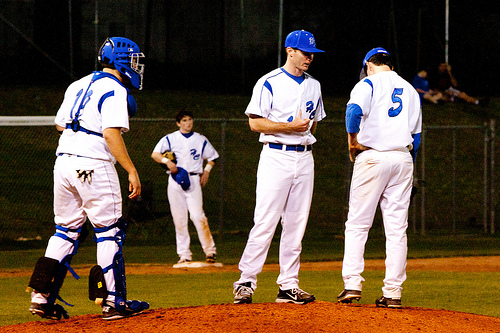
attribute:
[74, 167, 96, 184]
gloves — unused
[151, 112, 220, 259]
person — standing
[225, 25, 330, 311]
person — standing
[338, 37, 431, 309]
person — standing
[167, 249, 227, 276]
base plate — white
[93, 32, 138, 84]
helmet — blue 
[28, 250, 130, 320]
shin guards — black, protective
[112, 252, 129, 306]
shin guard — black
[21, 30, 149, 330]
person — standing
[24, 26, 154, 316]
catcher — black and blue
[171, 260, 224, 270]
base — white 